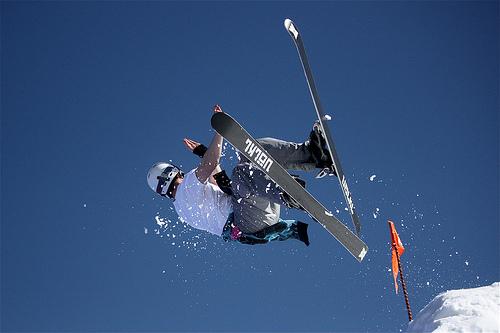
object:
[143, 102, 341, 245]
skier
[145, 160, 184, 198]
helmet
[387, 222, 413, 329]
flag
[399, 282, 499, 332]
snow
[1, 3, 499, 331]
air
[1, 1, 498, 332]
sky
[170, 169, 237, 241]
shirt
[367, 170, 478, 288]
snow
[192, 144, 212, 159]
gloves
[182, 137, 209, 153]
hands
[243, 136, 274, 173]
lettering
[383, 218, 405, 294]
orange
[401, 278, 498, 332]
pile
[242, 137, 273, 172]
logo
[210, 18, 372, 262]
bottom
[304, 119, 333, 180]
foot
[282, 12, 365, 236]
ski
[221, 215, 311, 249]
jacket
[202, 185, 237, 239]
waist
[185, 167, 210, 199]
short sleeves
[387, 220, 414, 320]
pole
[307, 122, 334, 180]
boot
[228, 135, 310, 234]
pants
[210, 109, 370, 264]
ski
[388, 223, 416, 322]
rod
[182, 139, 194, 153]
finger tips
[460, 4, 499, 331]
right